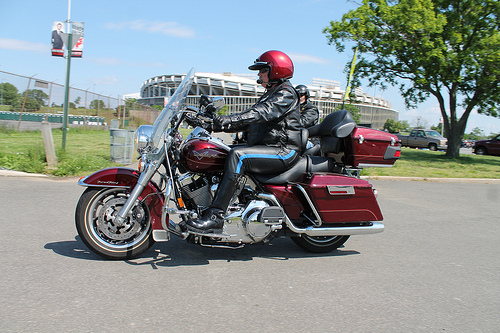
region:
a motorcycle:
[56, 30, 432, 267]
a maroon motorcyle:
[51, 24, 436, 255]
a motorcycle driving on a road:
[73, 53, 438, 276]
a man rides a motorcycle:
[66, 27, 483, 248]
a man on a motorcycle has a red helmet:
[59, 32, 441, 282]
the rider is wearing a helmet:
[78, 48, 443, 279]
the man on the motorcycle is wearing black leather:
[71, 45, 443, 276]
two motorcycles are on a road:
[87, 32, 448, 281]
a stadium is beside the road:
[118, 52, 439, 167]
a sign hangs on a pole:
[39, 8, 104, 150]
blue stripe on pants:
[216, 115, 303, 182]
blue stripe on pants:
[223, 145, 331, 205]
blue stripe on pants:
[213, 107, 355, 221]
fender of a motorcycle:
[73, 166, 133, 190]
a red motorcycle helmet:
[246, 44, 298, 89]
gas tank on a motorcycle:
[177, 140, 229, 178]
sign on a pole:
[43, 5, 93, 137]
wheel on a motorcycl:
[76, 192, 156, 264]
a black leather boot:
[176, 196, 243, 245]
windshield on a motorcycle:
[140, 69, 200, 163]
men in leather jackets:
[251, 46, 333, 133]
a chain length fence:
[6, 68, 54, 117]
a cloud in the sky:
[98, 10, 203, 43]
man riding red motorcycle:
[48, 60, 425, 277]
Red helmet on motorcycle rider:
[252, 53, 292, 80]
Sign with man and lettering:
[54, 15, 89, 58]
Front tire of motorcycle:
[61, 170, 155, 265]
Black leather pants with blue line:
[215, 131, 302, 178]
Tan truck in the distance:
[395, 120, 445, 158]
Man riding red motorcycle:
[89, 67, 396, 257]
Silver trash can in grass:
[95, 123, 140, 166]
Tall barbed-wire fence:
[2, 66, 126, 133]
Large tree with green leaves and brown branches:
[349, 2, 499, 163]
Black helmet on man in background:
[291, 81, 316, 101]